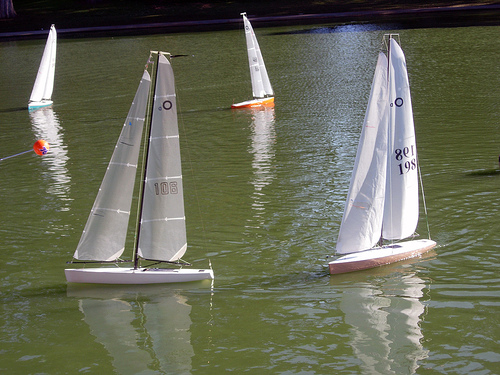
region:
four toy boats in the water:
[0, 0, 471, 335]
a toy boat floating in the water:
[61, 42, 206, 297]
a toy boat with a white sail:
[313, 17, 453, 280]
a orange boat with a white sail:
[223, 10, 278, 120]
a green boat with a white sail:
[16, 21, 69, 124]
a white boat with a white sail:
[38, 45, 219, 316]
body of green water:
[169, 255, 439, 373]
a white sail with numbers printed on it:
[336, 16, 435, 250]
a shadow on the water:
[456, 142, 493, 222]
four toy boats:
[0, 26, 452, 313]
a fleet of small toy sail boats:
[26, 14, 436, 284]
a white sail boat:
[61, 54, 215, 286]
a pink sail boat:
[327, 32, 435, 276]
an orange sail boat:
[231, 13, 276, 108]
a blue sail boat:
[28, 23, 57, 110]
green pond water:
[0, 8, 498, 374]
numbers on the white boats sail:
[153, 182, 178, 197]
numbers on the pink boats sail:
[392, 144, 416, 174]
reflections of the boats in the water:
[64, 269, 431, 372]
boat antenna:
[0, 141, 52, 161]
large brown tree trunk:
[0, 1, 20, 22]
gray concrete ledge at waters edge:
[70, 15, 210, 36]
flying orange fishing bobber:
[11, 120, 62, 170]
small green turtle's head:
[97, 25, 118, 45]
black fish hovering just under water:
[455, 145, 495, 190]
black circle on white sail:
[140, 85, 185, 120]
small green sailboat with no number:
[20, 17, 60, 117]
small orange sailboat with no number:
[226, 6, 273, 117]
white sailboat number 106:
[55, 40, 210, 307]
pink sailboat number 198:
[322, 22, 435, 292]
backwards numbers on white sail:
[388, 137, 423, 182]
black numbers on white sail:
[391, 141, 424, 175]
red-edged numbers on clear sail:
[150, 177, 183, 197]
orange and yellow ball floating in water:
[31, 131, 51, 156]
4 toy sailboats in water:
[20, 10, 455, 280]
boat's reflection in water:
[340, 265, 430, 370]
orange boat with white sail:
[230, 10, 275, 110]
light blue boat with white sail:
[25, 20, 60, 110]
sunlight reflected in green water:
[290, 20, 400, 256]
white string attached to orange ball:
[0, 130, 50, 170]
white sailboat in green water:
[56, 41, 218, 288]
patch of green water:
[226, 305, 349, 359]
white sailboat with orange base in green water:
[210, 5, 283, 117]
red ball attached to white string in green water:
[1, 136, 62, 165]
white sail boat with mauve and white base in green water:
[326, 29, 441, 278]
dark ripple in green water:
[434, 288, 498, 316]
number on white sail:
[150, 177, 180, 202]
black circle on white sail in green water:
[158, 96, 174, 113]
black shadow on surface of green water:
[258, 24, 360, 46]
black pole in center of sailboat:
[126, 53, 148, 273]